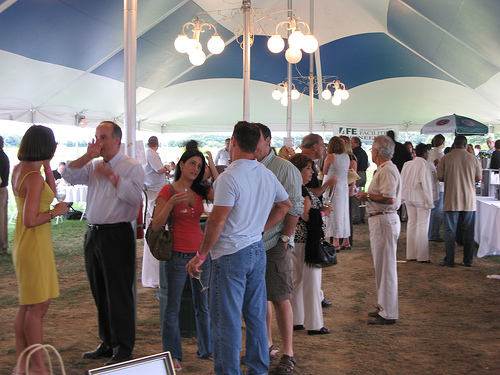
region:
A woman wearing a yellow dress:
[8, 122, 70, 369]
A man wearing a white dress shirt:
[59, 120, 152, 368]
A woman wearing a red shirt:
[146, 146, 232, 368]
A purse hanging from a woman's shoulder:
[144, 179, 179, 264]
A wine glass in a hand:
[184, 256, 212, 296]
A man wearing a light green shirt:
[236, 121, 304, 371]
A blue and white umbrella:
[420, 110, 489, 138]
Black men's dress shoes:
[76, 339, 141, 368]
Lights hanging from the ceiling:
[173, 0, 354, 111]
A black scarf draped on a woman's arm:
[304, 205, 329, 271]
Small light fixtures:
[259, 26, 321, 71]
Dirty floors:
[3, 228, 497, 373]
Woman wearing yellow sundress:
[7, 124, 69, 309]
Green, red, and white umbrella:
[412, 98, 492, 145]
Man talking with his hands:
[64, 118, 136, 226]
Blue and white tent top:
[0, 0, 497, 117]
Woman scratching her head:
[154, 143, 219, 240]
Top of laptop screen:
[85, 352, 185, 374]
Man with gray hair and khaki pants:
[362, 141, 402, 330]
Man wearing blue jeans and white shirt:
[205, 117, 274, 371]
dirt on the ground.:
[349, 338, 379, 349]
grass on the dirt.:
[62, 232, 72, 259]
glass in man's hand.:
[191, 267, 204, 294]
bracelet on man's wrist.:
[192, 250, 207, 263]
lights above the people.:
[187, 33, 224, 67]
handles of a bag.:
[27, 343, 56, 373]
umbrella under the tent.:
[424, 109, 481, 138]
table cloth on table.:
[485, 200, 498, 245]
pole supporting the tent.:
[121, 55, 143, 146]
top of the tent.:
[64, 10, 106, 40]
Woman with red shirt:
[167, 150, 212, 252]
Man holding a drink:
[188, 117, 281, 374]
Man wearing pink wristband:
[183, 120, 293, 373]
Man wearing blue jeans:
[186, 118, 283, 370]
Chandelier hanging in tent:
[172, 4, 319, 66]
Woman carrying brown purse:
[145, 135, 217, 363]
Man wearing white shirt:
[63, 118, 145, 365]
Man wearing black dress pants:
[63, 120, 152, 366]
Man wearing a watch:
[356, 130, 408, 323]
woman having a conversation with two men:
[147, 122, 301, 373]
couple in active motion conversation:
[8, 120, 143, 373]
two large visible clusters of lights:
[176, 8, 350, 107]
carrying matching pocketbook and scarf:
[305, 208, 338, 268]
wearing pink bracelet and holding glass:
[184, 252, 211, 291]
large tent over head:
[1, 0, 496, 131]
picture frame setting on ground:
[86, 351, 177, 373]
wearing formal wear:
[296, 161, 401, 331]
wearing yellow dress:
[13, 162, 59, 306]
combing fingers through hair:
[173, 148, 220, 207]